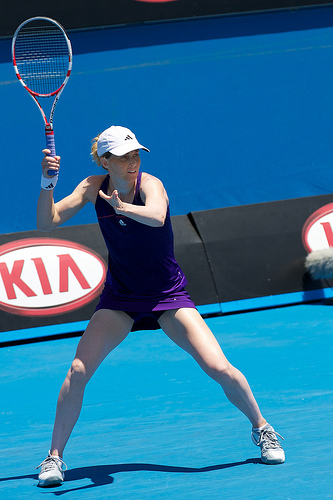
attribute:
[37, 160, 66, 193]
wristband — white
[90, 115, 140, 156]
hat — white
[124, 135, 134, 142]
logo — Adidas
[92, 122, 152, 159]
hat — white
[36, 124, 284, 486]
woman — playing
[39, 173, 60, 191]
wristband — white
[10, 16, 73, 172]
racket — red, white, blue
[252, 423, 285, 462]
shoe — white, athletic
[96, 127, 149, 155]
hat — white, baseball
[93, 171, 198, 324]
uniform — purple, tennis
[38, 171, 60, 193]
band — white, wrist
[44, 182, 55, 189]
logo — black, Adidas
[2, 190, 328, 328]
barrier — tennis, court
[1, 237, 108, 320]
logo — red, white, Kia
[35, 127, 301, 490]
player — female, tennis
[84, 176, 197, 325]
suit — purple, sport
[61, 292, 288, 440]
legs — toned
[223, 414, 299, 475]
foot — raised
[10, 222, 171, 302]
logo — background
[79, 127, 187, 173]
hat — white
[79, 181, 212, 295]
gear — purple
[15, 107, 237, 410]
woman — holding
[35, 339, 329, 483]
court — light blue